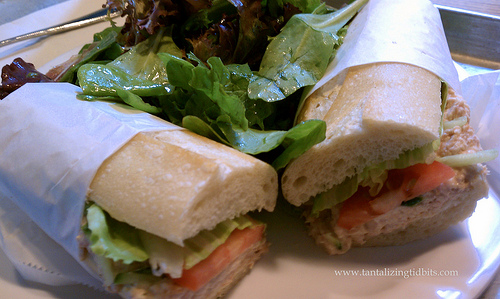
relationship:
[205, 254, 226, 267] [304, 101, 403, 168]
tomato in between bread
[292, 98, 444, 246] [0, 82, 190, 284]
sandwich wrapped in wrapping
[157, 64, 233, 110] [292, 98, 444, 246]
greens between sandwich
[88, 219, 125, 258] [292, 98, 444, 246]
lettuce on sandwich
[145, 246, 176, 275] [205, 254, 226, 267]
onion by tomato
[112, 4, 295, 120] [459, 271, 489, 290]
salad on plate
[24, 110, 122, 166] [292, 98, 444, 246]
wrapping on sandwich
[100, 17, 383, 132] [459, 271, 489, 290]
lunch on plate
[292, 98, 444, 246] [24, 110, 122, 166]
sandwich inside wrapping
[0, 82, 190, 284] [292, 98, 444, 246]
wrapping around sandwich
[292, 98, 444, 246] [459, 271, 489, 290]
sandwich on plate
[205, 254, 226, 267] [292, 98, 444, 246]
tomato inside sandwich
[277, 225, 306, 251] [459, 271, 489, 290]
shadow on plate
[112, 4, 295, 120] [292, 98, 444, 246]
salad between sandwich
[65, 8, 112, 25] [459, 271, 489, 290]
handle on plate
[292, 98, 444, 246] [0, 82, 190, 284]
sandwich in wrapping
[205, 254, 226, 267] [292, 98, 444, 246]
tomato in sandwich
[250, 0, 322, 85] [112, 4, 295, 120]
leaves are in salad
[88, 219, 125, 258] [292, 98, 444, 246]
lettuce are in sandwich